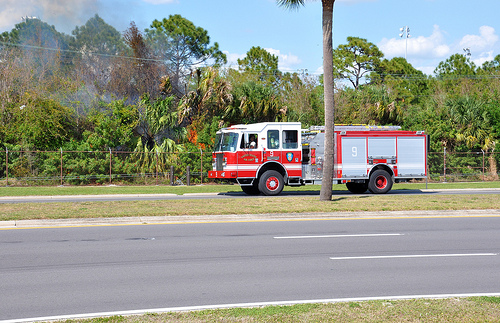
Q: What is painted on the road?
A: Lines.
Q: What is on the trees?
A: Fire.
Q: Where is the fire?
A: On trees.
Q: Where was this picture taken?
A: On road.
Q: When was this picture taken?
A: Afternoon.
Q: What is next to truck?
A: Tree.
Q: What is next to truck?
A: Fence.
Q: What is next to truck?
A: Street.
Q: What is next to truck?
A: Street.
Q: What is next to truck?
A: Fire.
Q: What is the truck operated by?
A: City.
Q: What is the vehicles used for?
A: Emergency.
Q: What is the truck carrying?
A: Ladders.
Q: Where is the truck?
A: In sunshine.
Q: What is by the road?
A: Palm tree.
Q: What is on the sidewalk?
A: Red fire truck.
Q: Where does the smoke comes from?
A: Woods.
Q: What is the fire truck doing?
A: Sitting in the road.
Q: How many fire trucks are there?
A: One.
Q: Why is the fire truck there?
A: There is a small fire.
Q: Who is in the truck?
A: Firefighters.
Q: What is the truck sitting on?
A: The road.